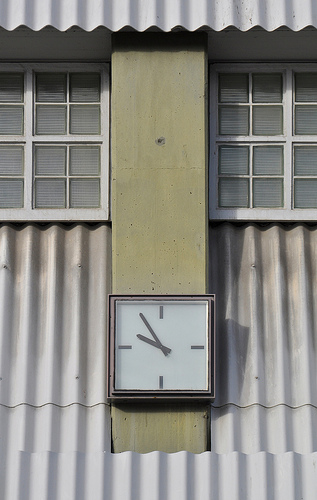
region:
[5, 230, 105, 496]
The siding is white.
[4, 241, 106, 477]
The siding is metal.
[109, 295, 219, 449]
The clock is on the pillar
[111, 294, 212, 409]
The clock face is white.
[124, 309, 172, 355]
The hands are black.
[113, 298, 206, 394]
The dashes are black.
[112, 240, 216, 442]
The pillare is gray.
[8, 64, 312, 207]
windows are on either side of the pillar.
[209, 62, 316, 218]
The frame is white.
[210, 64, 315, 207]
The windows are small.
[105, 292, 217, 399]
plain square clock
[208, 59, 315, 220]
window with white frame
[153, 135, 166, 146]
hole in cement beam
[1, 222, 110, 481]
white tin covers the wall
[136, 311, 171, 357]
two black hands on the clock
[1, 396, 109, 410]
seam of two pieces of tin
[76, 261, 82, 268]
screws holding pieces of tin on wall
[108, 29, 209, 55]
shadow of roof on cement pillar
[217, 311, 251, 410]
shadow of clock on tin siding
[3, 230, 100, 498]
tin siding has vertical ridges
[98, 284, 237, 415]
a square white clock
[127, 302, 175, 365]
clock's hands are black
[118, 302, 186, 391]
clock's hands are black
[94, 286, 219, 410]
A clock is on the wall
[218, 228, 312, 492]
Aluminum panels are on the wall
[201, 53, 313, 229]
A white window frame on the right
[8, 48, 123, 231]
A white window frame on the left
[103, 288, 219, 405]
A clock indicates the time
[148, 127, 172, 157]
A hole is in the wall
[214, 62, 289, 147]
The window has glass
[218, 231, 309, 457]
Aluminum plates line the walls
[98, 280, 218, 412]
The clock is silver and white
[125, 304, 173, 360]
The clock has a big hand and a small hand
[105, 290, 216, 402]
a square clock of a building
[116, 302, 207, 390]
the face of a clock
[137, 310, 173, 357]
the hands of a clock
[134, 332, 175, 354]
the hand of a clock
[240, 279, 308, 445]
the siding on a building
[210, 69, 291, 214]
the window of a building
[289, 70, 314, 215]
the window of a building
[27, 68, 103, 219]
the window of a building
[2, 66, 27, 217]
the window of a building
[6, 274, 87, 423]
the siding of a building